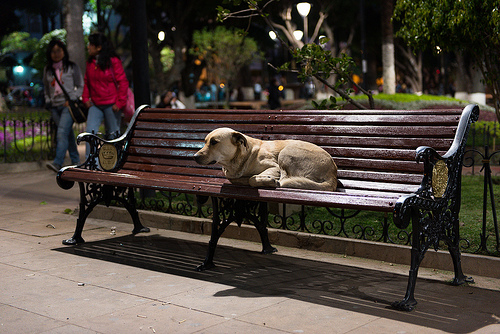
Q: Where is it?
A: This is at the park.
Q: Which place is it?
A: It is a park.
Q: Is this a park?
A: Yes, it is a park.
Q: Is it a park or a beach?
A: It is a park.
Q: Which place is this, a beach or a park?
A: It is a park.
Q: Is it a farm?
A: No, it is a park.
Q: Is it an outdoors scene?
A: Yes, it is outdoors.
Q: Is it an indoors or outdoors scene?
A: It is outdoors.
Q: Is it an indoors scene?
A: No, it is outdoors.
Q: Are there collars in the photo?
A: Yes, there is a collar.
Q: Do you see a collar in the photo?
A: Yes, there is a collar.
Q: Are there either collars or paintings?
A: Yes, there is a collar.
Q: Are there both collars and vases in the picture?
A: No, there is a collar but no vases.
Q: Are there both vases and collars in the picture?
A: No, there is a collar but no vases.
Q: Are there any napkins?
A: No, there are no napkins.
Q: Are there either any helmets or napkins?
A: No, there are no napkins or helmets.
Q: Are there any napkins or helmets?
A: No, there are no napkins or helmets.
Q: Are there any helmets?
A: No, there are no helmets.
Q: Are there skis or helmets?
A: No, there are no helmets or skis.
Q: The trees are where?
A: The trees are in the park.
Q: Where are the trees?
A: The trees are in the park.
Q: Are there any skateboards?
A: No, there are no skateboards.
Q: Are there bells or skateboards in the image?
A: No, there are no skateboards or bells.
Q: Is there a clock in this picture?
A: No, there are no clocks.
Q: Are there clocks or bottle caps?
A: No, there are no clocks or bottle caps.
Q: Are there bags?
A: Yes, there is a bag.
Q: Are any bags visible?
A: Yes, there is a bag.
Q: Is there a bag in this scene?
A: Yes, there is a bag.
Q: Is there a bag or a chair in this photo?
A: Yes, there is a bag.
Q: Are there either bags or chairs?
A: Yes, there is a bag.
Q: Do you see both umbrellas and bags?
A: No, there is a bag but no umbrellas.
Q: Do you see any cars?
A: No, there are no cars.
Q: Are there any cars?
A: No, there are no cars.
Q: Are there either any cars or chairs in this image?
A: No, there are no cars or chairs.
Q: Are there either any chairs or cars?
A: No, there are no cars or chairs.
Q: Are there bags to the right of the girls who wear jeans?
A: Yes, there is a bag to the right of the girls.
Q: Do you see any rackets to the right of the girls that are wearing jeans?
A: No, there is a bag to the right of the girls.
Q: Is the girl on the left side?
A: Yes, the girl is on the left of the image.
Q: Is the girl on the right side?
A: No, the girl is on the left of the image.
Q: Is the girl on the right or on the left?
A: The girl is on the left of the image.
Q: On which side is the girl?
A: The girl is on the left of the image.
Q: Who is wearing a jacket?
A: The girl is wearing a jacket.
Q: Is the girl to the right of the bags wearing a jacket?
A: Yes, the girl is wearing a jacket.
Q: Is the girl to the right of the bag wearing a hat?
A: No, the girl is wearing a jacket.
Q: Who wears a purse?
A: The girl wears a purse.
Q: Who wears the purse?
A: The girl wears a purse.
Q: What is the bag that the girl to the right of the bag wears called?
A: The bag is a purse.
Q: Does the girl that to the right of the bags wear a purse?
A: Yes, the girl wears a purse.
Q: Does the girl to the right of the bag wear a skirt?
A: No, the girl wears a purse.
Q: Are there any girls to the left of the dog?
A: Yes, there is a girl to the left of the dog.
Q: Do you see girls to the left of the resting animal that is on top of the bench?
A: Yes, there is a girl to the left of the dog.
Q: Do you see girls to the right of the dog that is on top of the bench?
A: No, the girl is to the left of the dog.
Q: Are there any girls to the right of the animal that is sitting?
A: No, the girl is to the left of the dog.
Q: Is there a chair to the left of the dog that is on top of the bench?
A: No, there is a girl to the left of the dog.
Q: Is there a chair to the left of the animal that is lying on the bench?
A: No, there is a girl to the left of the dog.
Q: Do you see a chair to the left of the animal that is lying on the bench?
A: No, there is a girl to the left of the dog.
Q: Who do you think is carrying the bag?
A: The girl is carrying the bag.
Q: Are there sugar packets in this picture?
A: No, there are no sugar packets.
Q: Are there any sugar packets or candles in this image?
A: No, there are no sugar packets or candles.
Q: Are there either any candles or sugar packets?
A: No, there are no sugar packets or candles.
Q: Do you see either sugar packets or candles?
A: No, there are no sugar packets or candles.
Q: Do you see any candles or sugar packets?
A: No, there are no sugar packets or candles.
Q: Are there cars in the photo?
A: No, there are no cars.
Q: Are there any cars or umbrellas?
A: No, there are no cars or umbrellas.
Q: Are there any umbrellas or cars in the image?
A: No, there are no cars or umbrellas.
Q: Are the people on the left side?
A: Yes, the people are on the left of the image.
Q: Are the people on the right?
A: No, the people are on the left of the image.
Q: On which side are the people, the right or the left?
A: The people are on the left of the image.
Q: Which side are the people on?
A: The people are on the left of the image.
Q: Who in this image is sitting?
A: The people are sitting.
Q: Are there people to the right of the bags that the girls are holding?
A: Yes, there are people to the right of the bags.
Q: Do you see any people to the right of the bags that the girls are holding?
A: Yes, there are people to the right of the bags.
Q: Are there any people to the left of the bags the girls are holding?
A: No, the people are to the right of the bags.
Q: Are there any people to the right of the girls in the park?
A: Yes, there are people to the right of the girls.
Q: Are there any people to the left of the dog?
A: Yes, there are people to the left of the dog.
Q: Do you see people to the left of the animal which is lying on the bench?
A: Yes, there are people to the left of the dog.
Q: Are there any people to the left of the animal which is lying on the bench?
A: Yes, there are people to the left of the dog.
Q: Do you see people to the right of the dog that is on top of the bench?
A: No, the people are to the left of the dog.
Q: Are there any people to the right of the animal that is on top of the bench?
A: No, the people are to the left of the dog.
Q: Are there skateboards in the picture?
A: No, there are no skateboards.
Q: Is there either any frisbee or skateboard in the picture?
A: No, there are no skateboards or frisbees.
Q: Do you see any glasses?
A: No, there are no glasses.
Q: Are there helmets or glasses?
A: No, there are no glasses or helmets.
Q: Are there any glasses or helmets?
A: No, there are no glasses or helmets.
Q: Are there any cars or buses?
A: No, there are no cars or buses.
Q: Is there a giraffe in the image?
A: No, there are no giraffes.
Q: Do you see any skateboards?
A: No, there are no skateboards.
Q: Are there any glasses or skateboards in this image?
A: No, there are no skateboards or glasses.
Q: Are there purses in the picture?
A: Yes, there is a purse.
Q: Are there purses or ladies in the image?
A: Yes, there is a purse.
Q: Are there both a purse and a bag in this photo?
A: Yes, there are both a purse and a bag.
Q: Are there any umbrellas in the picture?
A: No, there are no umbrellas.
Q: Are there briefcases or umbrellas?
A: No, there are no umbrellas or briefcases.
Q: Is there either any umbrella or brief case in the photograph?
A: No, there are no umbrellas or briefcases.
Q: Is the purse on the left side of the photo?
A: Yes, the purse is on the left of the image.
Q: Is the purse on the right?
A: No, the purse is on the left of the image.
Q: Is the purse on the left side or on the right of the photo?
A: The purse is on the left of the image.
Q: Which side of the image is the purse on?
A: The purse is on the left of the image.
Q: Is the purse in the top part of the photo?
A: Yes, the purse is in the top of the image.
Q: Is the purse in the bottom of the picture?
A: No, the purse is in the top of the image.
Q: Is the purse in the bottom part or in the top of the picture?
A: The purse is in the top of the image.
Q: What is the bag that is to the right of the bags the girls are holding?
A: The bag is a purse.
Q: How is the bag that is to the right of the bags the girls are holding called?
A: The bag is a purse.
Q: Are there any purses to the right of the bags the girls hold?
A: Yes, there is a purse to the right of the bags.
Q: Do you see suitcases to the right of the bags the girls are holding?
A: No, there is a purse to the right of the bags.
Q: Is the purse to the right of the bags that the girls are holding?
A: Yes, the purse is to the right of the bags.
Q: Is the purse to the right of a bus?
A: No, the purse is to the right of the bag.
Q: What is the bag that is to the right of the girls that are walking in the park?
A: The bag is a purse.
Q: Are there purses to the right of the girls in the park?
A: Yes, there is a purse to the right of the girls.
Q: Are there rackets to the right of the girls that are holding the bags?
A: No, there is a purse to the right of the girls.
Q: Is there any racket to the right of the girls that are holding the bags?
A: No, there is a purse to the right of the girls.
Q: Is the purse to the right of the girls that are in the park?
A: Yes, the purse is to the right of the girls.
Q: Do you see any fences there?
A: Yes, there is a fence.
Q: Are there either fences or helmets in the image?
A: Yes, there is a fence.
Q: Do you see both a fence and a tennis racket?
A: No, there is a fence but no rackets.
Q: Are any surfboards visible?
A: No, there are no surfboards.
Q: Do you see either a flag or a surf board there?
A: No, there are no surfboards or flags.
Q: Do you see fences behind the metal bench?
A: Yes, there is a fence behind the bench.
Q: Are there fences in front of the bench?
A: No, the fence is behind the bench.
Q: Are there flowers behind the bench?
A: No, there is a fence behind the bench.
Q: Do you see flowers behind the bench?
A: No, there is a fence behind the bench.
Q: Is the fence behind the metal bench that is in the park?
A: Yes, the fence is behind the bench.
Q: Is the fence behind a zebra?
A: No, the fence is behind the bench.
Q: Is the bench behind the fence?
A: No, the fence is behind the bench.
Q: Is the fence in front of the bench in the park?
A: No, the fence is behind the bench.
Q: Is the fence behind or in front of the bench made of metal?
A: The fence is behind the bench.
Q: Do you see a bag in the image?
A: Yes, there is a bag.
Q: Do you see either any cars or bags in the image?
A: Yes, there is a bag.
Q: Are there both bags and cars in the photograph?
A: No, there is a bag but no cars.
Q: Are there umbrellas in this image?
A: No, there are no umbrellas.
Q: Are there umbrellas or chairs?
A: No, there are no umbrellas or chairs.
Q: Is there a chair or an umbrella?
A: No, there are no umbrellas or chairs.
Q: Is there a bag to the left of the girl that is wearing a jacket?
A: Yes, there is a bag to the left of the girl.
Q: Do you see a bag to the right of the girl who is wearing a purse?
A: No, the bag is to the left of the girl.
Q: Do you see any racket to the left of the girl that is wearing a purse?
A: No, there is a bag to the left of the girl.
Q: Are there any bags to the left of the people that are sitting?
A: Yes, there is a bag to the left of the people.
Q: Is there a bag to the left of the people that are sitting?
A: Yes, there is a bag to the left of the people.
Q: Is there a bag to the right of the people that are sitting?
A: No, the bag is to the left of the people.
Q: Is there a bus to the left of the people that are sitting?
A: No, there is a bag to the left of the people.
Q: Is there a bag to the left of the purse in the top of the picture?
A: Yes, there is a bag to the left of the purse.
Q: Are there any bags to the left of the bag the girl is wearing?
A: Yes, there is a bag to the left of the purse.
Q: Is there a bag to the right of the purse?
A: No, the bag is to the left of the purse.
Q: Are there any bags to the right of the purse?
A: No, the bag is to the left of the purse.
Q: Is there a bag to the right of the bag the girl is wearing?
A: No, the bag is to the left of the purse.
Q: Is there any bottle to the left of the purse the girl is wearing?
A: No, there is a bag to the left of the purse.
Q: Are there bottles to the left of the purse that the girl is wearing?
A: No, there is a bag to the left of the purse.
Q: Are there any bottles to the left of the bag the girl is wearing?
A: No, there is a bag to the left of the purse.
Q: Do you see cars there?
A: No, there are no cars.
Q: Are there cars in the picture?
A: No, there are no cars.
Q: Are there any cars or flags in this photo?
A: No, there are no cars or flags.